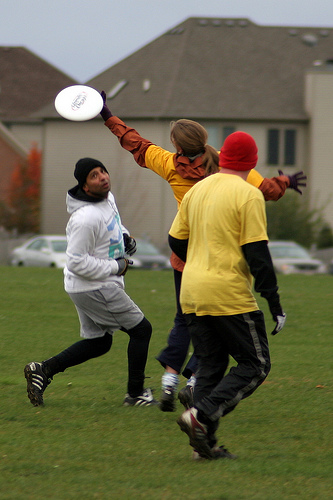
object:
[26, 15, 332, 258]
house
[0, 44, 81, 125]
roof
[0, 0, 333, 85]
sky